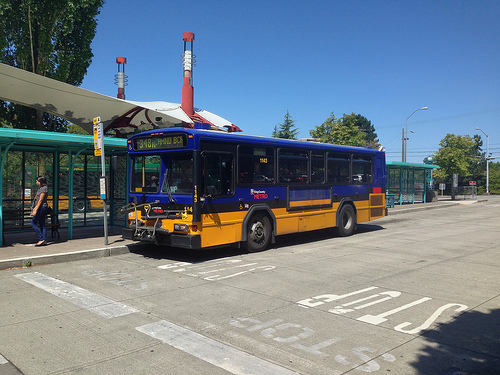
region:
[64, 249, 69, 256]
edge of a road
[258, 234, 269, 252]
part of a wheel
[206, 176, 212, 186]
part of a window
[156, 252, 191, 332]
edge of a path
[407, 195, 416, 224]
part of a pavement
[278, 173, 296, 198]
side of a bus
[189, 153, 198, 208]
edge of a bus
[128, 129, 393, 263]
Yellow and blue public transit bus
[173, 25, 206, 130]
Decorative light post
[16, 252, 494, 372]
Pedestrian cross walk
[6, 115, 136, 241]
Pedestrian shelter for pick-up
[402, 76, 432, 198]
Tall silver street lamp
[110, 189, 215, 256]
Bus bicycle rack to store bikes for riding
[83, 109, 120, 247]
Bus stop informational sign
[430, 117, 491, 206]
Distant tree at a street corner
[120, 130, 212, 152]
Digital sign for bus route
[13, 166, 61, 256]
Pedestrian woman departing bus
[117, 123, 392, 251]
Purple and gold passenger bus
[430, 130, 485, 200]
tall tree in the distance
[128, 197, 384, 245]
gold part of bus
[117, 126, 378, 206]
Purple part of bus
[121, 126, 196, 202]
Front windshield of bus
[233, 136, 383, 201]
Passenger windows on left side of bus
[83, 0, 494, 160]
Clear blue sky day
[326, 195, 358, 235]
Left rear tire of bus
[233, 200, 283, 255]
Left front wheel of bus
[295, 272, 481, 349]
Traffic instructions on street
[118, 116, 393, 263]
A large bus that is blue and yellow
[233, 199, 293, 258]
Front wheel on bus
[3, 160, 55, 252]
Lady standing outside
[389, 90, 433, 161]
Street light behind building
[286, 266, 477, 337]
White lettering on street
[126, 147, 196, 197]
Windshield on bus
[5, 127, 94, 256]
Awning outside bus terminal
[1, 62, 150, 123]
White awning over awning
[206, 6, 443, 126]
No clouds in the sky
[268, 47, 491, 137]
The sky is blue and no clouds are visible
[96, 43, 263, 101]
Tall red poles sticking out of white roof.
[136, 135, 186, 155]
Green writing on front of bus.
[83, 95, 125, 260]
Street sign on sidewalk.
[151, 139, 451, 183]
Top section of bus is blue.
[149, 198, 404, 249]
Bottom section of bus is yellow.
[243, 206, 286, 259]
Black wheel on bus.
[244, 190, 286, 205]
Red writing on side of bus.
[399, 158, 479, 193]
Green overhang for bus stop.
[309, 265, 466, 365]
White writing in road.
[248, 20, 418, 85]
Sky is clear and blue.